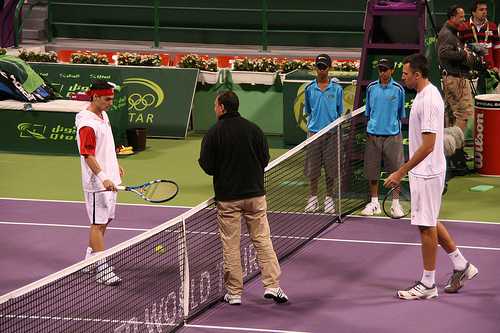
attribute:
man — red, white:
[74, 77, 129, 286]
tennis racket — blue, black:
[111, 178, 179, 204]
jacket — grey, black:
[196, 111, 271, 200]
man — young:
[302, 53, 344, 217]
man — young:
[362, 57, 407, 220]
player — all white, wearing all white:
[384, 52, 480, 300]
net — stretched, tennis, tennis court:
[0, 101, 372, 332]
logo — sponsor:
[15, 120, 83, 142]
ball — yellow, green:
[154, 242, 166, 255]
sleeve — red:
[77, 124, 97, 160]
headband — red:
[84, 86, 118, 98]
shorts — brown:
[303, 129, 345, 183]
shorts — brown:
[361, 130, 409, 183]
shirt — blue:
[301, 77, 343, 136]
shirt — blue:
[363, 75, 405, 135]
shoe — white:
[304, 193, 319, 213]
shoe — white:
[320, 193, 340, 213]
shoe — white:
[359, 200, 384, 216]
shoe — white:
[388, 199, 406, 218]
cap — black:
[314, 52, 333, 69]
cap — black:
[373, 56, 395, 69]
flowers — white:
[68, 47, 109, 66]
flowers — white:
[114, 50, 165, 70]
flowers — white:
[174, 49, 219, 73]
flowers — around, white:
[227, 51, 284, 72]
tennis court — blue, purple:
[1, 132, 500, 332]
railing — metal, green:
[12, 0, 499, 48]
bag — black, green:
[0, 54, 63, 104]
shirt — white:
[403, 81, 448, 177]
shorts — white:
[407, 168, 450, 224]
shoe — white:
[93, 261, 123, 287]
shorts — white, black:
[85, 186, 121, 225]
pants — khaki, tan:
[215, 195, 284, 294]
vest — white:
[73, 108, 123, 190]